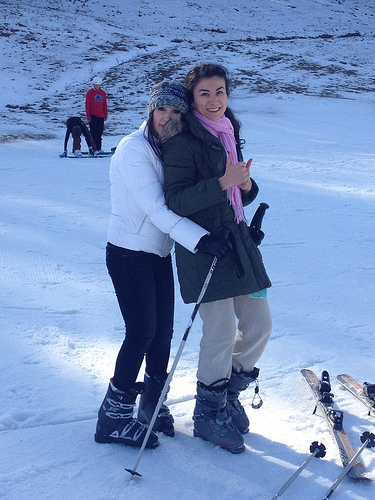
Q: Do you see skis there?
A: Yes, there are skis.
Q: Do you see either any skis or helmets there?
A: Yes, there are skis.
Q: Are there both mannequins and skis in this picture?
A: No, there are skis but no mannequins.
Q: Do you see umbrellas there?
A: No, there are no umbrellas.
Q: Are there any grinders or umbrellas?
A: No, there are no umbrellas or grinders.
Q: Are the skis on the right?
A: Yes, the skis are on the right of the image.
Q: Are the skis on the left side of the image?
A: No, the skis are on the right of the image.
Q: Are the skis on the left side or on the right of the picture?
A: The skis are on the right of the image.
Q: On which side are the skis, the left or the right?
A: The skis are on the right of the image.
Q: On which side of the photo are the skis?
A: The skis are on the right of the image.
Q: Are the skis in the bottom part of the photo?
A: Yes, the skis are in the bottom of the image.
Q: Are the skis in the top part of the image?
A: No, the skis are in the bottom of the image.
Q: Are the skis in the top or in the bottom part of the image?
A: The skis are in the bottom of the image.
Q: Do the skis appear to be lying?
A: Yes, the skis are lying.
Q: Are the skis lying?
A: Yes, the skis are lying.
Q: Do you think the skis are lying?
A: Yes, the skis are lying.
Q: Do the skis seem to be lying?
A: Yes, the skis are lying.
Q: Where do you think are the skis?
A: The skis are on the snow.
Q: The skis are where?
A: The skis are on the snow.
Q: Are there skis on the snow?
A: Yes, there are skis on the snow.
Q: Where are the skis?
A: The skis are in the snow.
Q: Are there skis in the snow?
A: Yes, there are skis in the snow.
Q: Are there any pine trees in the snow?
A: No, there are skis in the snow.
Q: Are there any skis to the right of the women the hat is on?
A: Yes, there are skis to the right of the women.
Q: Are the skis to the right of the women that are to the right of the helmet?
A: Yes, the skis are to the right of the women.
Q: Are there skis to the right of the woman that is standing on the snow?
A: Yes, there are skis to the right of the woman.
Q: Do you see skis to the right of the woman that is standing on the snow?
A: Yes, there are skis to the right of the woman.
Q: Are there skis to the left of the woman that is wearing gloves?
A: No, the skis are to the right of the woman.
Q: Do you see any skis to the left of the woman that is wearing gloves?
A: No, the skis are to the right of the woman.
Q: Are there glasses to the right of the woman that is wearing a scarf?
A: No, there are skis to the right of the woman.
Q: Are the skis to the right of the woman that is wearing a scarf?
A: Yes, the skis are to the right of the woman.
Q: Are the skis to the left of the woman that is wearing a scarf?
A: No, the skis are to the right of the woman.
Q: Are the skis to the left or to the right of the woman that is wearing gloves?
A: The skis are to the right of the woman.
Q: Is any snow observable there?
A: Yes, there is snow.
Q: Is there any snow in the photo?
A: Yes, there is snow.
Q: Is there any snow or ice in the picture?
A: Yes, there is snow.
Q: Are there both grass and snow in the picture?
A: No, there is snow but no grass.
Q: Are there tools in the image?
A: No, there are no tools.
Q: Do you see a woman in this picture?
A: Yes, there are women.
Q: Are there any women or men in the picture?
A: Yes, there are women.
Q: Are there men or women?
A: Yes, there are women.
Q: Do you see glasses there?
A: No, there are no glasses.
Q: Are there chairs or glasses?
A: No, there are no glasses or chairs.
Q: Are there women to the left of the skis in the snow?
A: Yes, there are women to the left of the skis.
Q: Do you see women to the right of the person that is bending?
A: Yes, there are women to the right of the person.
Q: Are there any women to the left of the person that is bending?
A: No, the women are to the right of the person.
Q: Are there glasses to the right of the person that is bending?
A: No, there are women to the right of the person.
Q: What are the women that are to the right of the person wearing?
A: The women are wearing boots.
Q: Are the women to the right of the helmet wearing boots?
A: Yes, the women are wearing boots.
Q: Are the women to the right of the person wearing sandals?
A: No, the women are wearing boots.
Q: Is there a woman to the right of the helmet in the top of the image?
A: Yes, there are women to the right of the helmet.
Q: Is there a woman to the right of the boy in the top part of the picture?
A: Yes, there are women to the right of the boy.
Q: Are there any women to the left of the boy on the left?
A: No, the women are to the right of the boy.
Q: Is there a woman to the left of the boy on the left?
A: No, the women are to the right of the boy.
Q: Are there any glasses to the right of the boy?
A: No, there are women to the right of the boy.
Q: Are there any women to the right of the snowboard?
A: Yes, there are women to the right of the snowboard.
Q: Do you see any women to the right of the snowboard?
A: Yes, there are women to the right of the snowboard.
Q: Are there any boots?
A: Yes, there are boots.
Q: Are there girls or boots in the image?
A: Yes, there are boots.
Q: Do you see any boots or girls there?
A: Yes, there are boots.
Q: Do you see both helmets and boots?
A: Yes, there are both boots and a helmet.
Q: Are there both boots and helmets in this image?
A: Yes, there are both boots and a helmet.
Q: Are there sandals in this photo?
A: No, there are no sandals.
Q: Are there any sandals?
A: No, there are no sandals.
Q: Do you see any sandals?
A: No, there are no sandals.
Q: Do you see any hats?
A: Yes, there is a hat.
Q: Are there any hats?
A: Yes, there is a hat.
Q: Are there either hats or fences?
A: Yes, there is a hat.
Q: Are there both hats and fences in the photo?
A: No, there is a hat but no fences.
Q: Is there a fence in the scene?
A: No, there are no fences.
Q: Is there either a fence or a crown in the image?
A: No, there are no fences or crowns.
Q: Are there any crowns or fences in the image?
A: No, there are no fences or crowns.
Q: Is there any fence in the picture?
A: No, there are no fences.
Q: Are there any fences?
A: No, there are no fences.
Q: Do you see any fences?
A: No, there are no fences.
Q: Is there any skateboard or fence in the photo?
A: No, there are no fences or skateboards.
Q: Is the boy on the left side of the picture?
A: Yes, the boy is on the left of the image.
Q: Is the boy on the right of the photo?
A: No, the boy is on the left of the image.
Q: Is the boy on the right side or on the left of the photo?
A: The boy is on the left of the image.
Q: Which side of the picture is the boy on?
A: The boy is on the left of the image.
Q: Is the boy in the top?
A: Yes, the boy is in the top of the image.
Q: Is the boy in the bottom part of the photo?
A: No, the boy is in the top of the image.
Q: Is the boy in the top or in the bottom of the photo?
A: The boy is in the top of the image.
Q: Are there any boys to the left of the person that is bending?
A: Yes, there is a boy to the left of the person.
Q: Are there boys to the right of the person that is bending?
A: No, the boy is to the left of the person.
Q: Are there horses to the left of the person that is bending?
A: No, there is a boy to the left of the person.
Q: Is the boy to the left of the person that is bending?
A: Yes, the boy is to the left of the person.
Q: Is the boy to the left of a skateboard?
A: No, the boy is to the left of the person.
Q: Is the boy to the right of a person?
A: No, the boy is to the left of a person.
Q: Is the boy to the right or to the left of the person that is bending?
A: The boy is to the left of the person.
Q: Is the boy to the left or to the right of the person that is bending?
A: The boy is to the left of the person.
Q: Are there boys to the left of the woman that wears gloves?
A: Yes, there is a boy to the left of the woman.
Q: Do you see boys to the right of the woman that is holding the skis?
A: No, the boy is to the left of the woman.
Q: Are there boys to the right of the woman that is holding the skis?
A: No, the boy is to the left of the woman.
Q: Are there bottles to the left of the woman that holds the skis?
A: No, there is a boy to the left of the woman.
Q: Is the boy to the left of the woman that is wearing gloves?
A: Yes, the boy is to the left of the woman.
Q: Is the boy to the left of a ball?
A: No, the boy is to the left of the woman.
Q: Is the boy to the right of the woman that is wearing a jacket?
A: No, the boy is to the left of the woman.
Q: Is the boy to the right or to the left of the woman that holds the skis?
A: The boy is to the left of the woman.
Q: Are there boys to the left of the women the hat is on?
A: Yes, there is a boy to the left of the women.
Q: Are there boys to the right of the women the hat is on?
A: No, the boy is to the left of the women.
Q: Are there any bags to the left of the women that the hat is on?
A: No, there is a boy to the left of the women.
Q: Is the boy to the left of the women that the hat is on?
A: Yes, the boy is to the left of the women.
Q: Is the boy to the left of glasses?
A: No, the boy is to the left of the women.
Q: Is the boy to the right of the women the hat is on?
A: No, the boy is to the left of the women.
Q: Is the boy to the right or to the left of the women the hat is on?
A: The boy is to the left of the women.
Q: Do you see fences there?
A: No, there are no fences.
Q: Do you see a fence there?
A: No, there are no fences.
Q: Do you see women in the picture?
A: Yes, there is a woman.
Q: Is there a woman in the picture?
A: Yes, there is a woman.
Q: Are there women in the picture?
A: Yes, there is a woman.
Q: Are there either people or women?
A: Yes, there is a woman.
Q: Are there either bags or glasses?
A: No, there are no glasses or bags.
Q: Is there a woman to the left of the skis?
A: Yes, there is a woman to the left of the skis.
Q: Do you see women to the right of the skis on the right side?
A: No, the woman is to the left of the skis.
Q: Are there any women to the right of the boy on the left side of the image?
A: Yes, there is a woman to the right of the boy.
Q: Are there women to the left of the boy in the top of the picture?
A: No, the woman is to the right of the boy.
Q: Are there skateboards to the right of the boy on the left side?
A: No, there is a woman to the right of the boy.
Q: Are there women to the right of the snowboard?
A: Yes, there is a woman to the right of the snowboard.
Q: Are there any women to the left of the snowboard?
A: No, the woman is to the right of the snowboard.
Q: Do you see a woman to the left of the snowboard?
A: No, the woman is to the right of the snowboard.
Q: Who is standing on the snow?
A: The woman is standing on the snow.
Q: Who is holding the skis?
A: The woman is holding the skis.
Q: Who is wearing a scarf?
A: The woman is wearing a scarf.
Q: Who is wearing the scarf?
A: The woman is wearing a scarf.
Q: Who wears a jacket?
A: The woman wears a jacket.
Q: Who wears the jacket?
A: The woman wears a jacket.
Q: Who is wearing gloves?
A: The woman is wearing gloves.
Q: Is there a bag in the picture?
A: No, there are no bags.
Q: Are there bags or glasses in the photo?
A: No, there are no bags or glasses.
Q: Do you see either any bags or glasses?
A: No, there are no bags or glasses.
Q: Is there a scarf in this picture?
A: Yes, there is a scarf.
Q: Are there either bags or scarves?
A: Yes, there is a scarf.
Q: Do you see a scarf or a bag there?
A: Yes, there is a scarf.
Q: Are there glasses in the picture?
A: No, there are no glasses.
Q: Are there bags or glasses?
A: No, there are no glasses or bags.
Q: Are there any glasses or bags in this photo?
A: No, there are no glasses or bags.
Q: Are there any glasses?
A: No, there are no glasses.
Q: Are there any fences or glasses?
A: No, there are no glasses or fences.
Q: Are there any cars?
A: No, there are no cars.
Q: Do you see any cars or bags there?
A: No, there are no cars or bags.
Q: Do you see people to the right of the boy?
A: Yes, there is a person to the right of the boy.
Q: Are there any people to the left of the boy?
A: No, the person is to the right of the boy.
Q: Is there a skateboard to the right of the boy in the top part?
A: No, there is a person to the right of the boy.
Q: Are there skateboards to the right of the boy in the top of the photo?
A: No, there is a person to the right of the boy.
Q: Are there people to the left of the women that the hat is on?
A: Yes, there is a person to the left of the women.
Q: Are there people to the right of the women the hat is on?
A: No, the person is to the left of the women.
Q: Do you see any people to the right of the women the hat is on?
A: No, the person is to the left of the women.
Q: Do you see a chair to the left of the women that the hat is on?
A: No, there is a person to the left of the women.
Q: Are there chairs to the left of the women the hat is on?
A: No, there is a person to the left of the women.